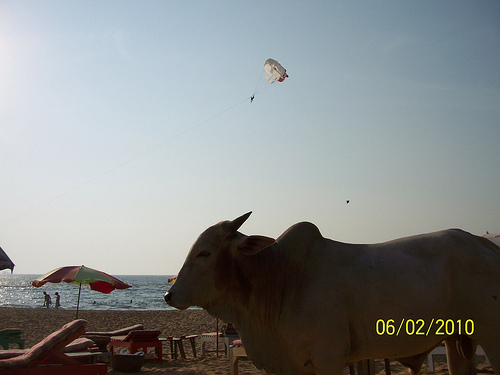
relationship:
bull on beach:
[174, 228, 494, 369] [152, 315, 175, 328]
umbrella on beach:
[51, 264, 116, 316] [152, 315, 175, 328]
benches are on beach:
[116, 323, 203, 360] [152, 315, 175, 328]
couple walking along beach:
[35, 289, 61, 304] [152, 315, 175, 328]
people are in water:
[55, 295, 67, 312] [139, 287, 154, 300]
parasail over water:
[263, 55, 285, 84] [139, 287, 154, 300]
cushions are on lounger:
[111, 328, 125, 339] [130, 332, 160, 357]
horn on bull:
[231, 210, 246, 229] [174, 228, 494, 369]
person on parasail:
[241, 93, 258, 107] [263, 55, 285, 84]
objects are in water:
[161, 269, 178, 286] [139, 287, 154, 300]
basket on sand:
[1, 333, 21, 347] [125, 316, 151, 324]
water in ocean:
[139, 287, 154, 300] [125, 294, 145, 302]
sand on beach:
[125, 316, 151, 324] [152, 315, 175, 328]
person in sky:
[241, 93, 258, 107] [94, 7, 138, 32]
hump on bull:
[306, 225, 415, 258] [174, 228, 494, 369]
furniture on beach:
[123, 325, 201, 355] [152, 315, 175, 328]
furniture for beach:
[123, 325, 201, 355] [152, 315, 175, 328]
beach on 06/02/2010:
[152, 315, 175, 328] [368, 314, 473, 342]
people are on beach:
[55, 295, 67, 312] [152, 315, 175, 328]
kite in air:
[273, 67, 290, 84] [305, 54, 376, 115]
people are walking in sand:
[55, 295, 67, 312] [125, 316, 151, 324]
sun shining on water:
[8, 280, 30, 291] [139, 287, 154, 300]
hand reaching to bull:
[41, 298, 46, 302] [174, 228, 494, 369]